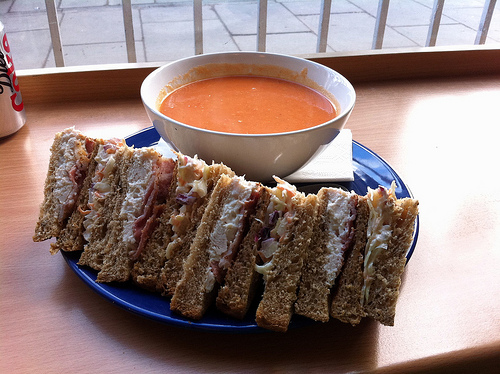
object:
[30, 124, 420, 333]
sandwich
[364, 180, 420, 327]
bread